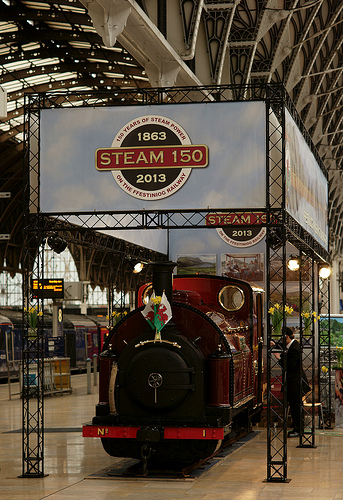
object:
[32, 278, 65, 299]
sign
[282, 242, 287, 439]
pole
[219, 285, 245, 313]
window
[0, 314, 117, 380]
train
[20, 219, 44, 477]
pole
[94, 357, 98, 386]
metal pole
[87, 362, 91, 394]
metal pole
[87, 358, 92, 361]
blue top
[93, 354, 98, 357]
blue top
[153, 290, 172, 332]
flags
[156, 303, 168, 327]
dragons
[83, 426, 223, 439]
stripe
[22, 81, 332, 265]
canopy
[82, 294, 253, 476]
steam engine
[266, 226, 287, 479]
pole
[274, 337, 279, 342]
flower pot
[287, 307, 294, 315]
flower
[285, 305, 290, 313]
flower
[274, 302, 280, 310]
flower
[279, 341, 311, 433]
suit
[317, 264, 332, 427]
pole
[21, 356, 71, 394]
cart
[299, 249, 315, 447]
pole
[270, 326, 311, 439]
man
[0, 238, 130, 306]
window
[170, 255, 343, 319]
wall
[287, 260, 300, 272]
lights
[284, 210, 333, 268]
beams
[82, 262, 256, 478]
engine display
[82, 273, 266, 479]
red train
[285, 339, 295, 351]
shirt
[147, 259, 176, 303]
smokestack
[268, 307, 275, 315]
flowers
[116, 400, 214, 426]
black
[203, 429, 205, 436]
i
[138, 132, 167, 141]
1863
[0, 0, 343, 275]
background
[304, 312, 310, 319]
flowers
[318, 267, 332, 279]
lights